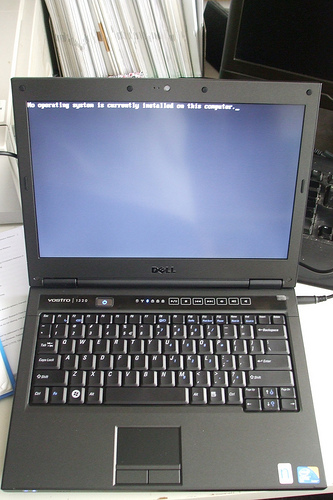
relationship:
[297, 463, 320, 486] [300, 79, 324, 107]
windows symbol in corner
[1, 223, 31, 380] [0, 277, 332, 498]
papers on table